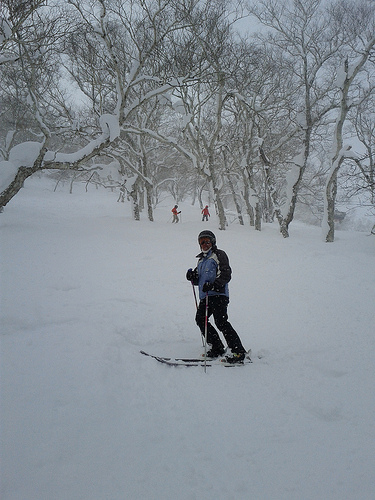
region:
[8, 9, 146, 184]
snow covered tree branches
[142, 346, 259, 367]
snow skis partially covered in snow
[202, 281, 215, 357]
red and white ski pole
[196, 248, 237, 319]
man's black and white ski jacket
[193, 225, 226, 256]
man wearing ski goggles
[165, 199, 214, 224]
two people wearing red jackets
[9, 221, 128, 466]
white clean snow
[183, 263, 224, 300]
pair of black men's ski gloves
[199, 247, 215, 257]
top of man's white undershirt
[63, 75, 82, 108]
portion of gray skies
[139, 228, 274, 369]
a person riding skis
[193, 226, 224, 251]
a human head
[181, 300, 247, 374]
a pair of pants on a person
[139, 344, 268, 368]
a pair of snow covered skis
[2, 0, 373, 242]
a forest of snow covered trees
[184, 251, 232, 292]
a man wearing a ski jacket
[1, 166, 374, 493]
a snow covered ground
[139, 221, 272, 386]
a man dressed in ski equipment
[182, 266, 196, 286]
a human hand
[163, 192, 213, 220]
people riding skis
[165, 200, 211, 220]
skiers wearing red jackets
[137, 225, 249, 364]
man on dark-colored skis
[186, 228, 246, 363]
man wearing a black hat, blue jacket, and black pants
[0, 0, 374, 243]
trees covered in snow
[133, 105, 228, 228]
people between tall trees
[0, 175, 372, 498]
ground covered by snow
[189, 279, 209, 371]
red and white ski poles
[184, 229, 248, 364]
man is wearing goggles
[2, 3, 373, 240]
brown trees are bare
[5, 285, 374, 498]
snow is messed up by skis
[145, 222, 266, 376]
a man skiing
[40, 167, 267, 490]
a steep snow hill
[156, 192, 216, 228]
two people on top of the ski hill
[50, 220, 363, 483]
a ground full of snow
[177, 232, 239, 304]
a man wearing a blue jacket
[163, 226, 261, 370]
a man on ski's leaning to the side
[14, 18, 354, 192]
a lot of trees covered in snow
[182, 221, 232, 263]
a man wearing a helmet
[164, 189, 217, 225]
two people coming down the hill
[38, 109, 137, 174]
a snow covered branch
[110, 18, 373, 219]
snow covered trees on a mountain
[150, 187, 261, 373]
three people snow skiing in winter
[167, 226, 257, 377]
one skier with blue jacket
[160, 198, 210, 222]
two skiers with red jackets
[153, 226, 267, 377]
skier leaning on ski poles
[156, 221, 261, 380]
skier skidding to a stop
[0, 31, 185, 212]
beautiful tree laden with snow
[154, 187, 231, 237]
two skiers off in the distance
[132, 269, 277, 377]
snow boots, skis and poles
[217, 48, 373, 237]
forest of trees covered in snow